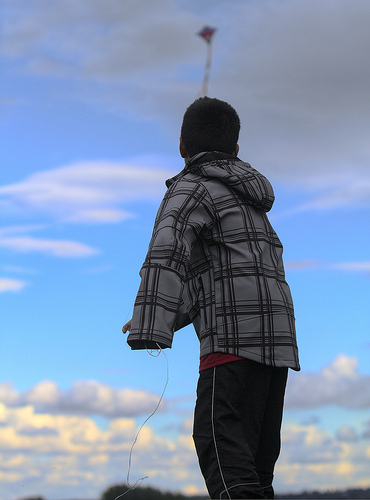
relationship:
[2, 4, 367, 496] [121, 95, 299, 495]
picture of a boy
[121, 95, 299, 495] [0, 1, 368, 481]
boy looking to sky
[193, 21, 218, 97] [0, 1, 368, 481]
kite in sky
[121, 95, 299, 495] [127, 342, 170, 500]
boy holds string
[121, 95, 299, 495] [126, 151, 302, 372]
boy wears jacket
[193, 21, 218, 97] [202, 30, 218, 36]
kite has red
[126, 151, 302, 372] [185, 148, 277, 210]
jacket has hood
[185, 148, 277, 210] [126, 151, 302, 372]
hood on jacket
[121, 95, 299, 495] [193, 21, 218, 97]
boy flying kite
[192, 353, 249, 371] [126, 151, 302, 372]
shirt shows below jacket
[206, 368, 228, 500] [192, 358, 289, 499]
lines on pants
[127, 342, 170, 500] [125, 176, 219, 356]
string below sleeve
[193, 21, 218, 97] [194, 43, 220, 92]
kite with tail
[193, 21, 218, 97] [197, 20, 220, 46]
kite shaped like diamond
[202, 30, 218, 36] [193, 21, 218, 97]
red on kite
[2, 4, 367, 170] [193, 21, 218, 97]
top clouds grey near kite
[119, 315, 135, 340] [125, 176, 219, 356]
finger curled behind sleeve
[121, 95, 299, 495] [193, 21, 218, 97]
boy watches kite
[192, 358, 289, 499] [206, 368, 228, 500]
pants have white lines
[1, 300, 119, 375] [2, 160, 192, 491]
blue shows behind clouds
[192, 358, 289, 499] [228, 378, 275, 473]
pants made in black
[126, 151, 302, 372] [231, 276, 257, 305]
jacket mostly grey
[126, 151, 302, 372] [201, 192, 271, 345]
jacket has a pattern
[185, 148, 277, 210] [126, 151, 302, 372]
hood attached to jacket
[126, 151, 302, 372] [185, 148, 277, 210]
jacket has a hood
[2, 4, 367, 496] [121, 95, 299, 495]
picture of one boy